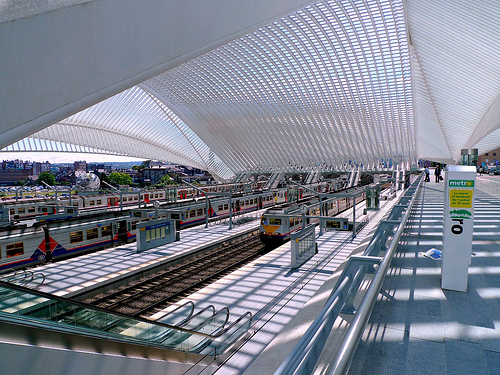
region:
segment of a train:
[3, 232, 45, 259]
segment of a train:
[133, 221, 169, 242]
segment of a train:
[184, 201, 200, 218]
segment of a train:
[215, 198, 235, 213]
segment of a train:
[240, 197, 252, 209]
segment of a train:
[64, 197, 82, 214]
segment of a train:
[89, 192, 106, 206]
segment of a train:
[124, 192, 141, 209]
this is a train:
[49, 222, 101, 247]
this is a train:
[177, 202, 209, 220]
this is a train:
[211, 193, 228, 212]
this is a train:
[10, 202, 51, 219]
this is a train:
[61, 187, 81, 210]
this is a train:
[120, 184, 169, 196]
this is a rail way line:
[215, 234, 261, 269]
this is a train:
[252, 188, 328, 233]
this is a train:
[4, 188, 84, 225]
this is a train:
[1, 226, 71, 269]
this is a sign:
[445, 171, 471, 246]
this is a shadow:
[395, 290, 455, 330]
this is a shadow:
[395, 260, 445, 292]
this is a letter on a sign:
[450, 221, 463, 233]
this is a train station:
[5, 4, 485, 371]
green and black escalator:
[2, 265, 260, 373]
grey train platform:
[0, 216, 224, 296]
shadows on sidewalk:
[377, 215, 492, 372]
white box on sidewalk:
[435, 156, 487, 297]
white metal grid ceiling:
[157, 28, 424, 177]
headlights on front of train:
[257, 228, 284, 240]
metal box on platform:
[275, 214, 330, 274]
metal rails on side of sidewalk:
[280, 176, 418, 371]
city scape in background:
[2, 157, 177, 194]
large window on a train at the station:
[65, 227, 85, 247]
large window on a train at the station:
[82, 223, 101, 245]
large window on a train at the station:
[100, 223, 114, 238]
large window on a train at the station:
[4, 239, 28, 261]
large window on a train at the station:
[187, 206, 198, 221]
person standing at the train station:
[421, 164, 431, 185]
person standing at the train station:
[430, 159, 447, 185]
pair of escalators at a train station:
[1, 262, 256, 374]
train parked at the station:
[260, 177, 380, 244]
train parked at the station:
[0, 170, 344, 280]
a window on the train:
[72, 227, 86, 247]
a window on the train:
[90, 218, 120, 248]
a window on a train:
[4, 241, 24, 258]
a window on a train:
[67, 224, 87, 247]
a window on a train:
[87, 227, 104, 240]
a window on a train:
[102, 224, 111, 234]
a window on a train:
[7, 203, 17, 212]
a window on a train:
[15, 207, 23, 212]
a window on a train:
[37, 199, 49, 216]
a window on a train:
[84, 194, 96, 209]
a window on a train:
[92, 199, 102, 207]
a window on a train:
[188, 201, 195, 218]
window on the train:
[72, 228, 93, 236]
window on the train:
[8, 240, 20, 256]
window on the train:
[84, 226, 101, 256]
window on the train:
[101, 227, 110, 247]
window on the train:
[184, 212, 193, 218]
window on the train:
[195, 208, 201, 220]